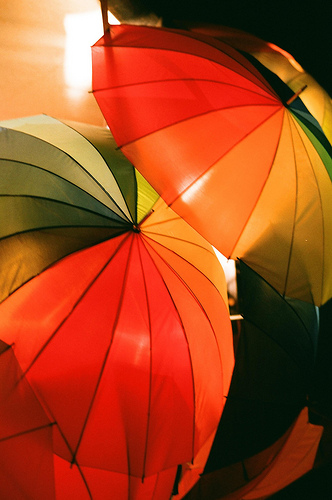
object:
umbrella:
[92, 23, 331, 306]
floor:
[184, 409, 332, 497]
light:
[66, 14, 121, 94]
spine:
[136, 208, 154, 230]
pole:
[97, 3, 108, 30]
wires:
[115, 101, 282, 155]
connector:
[284, 82, 306, 108]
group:
[3, 23, 329, 500]